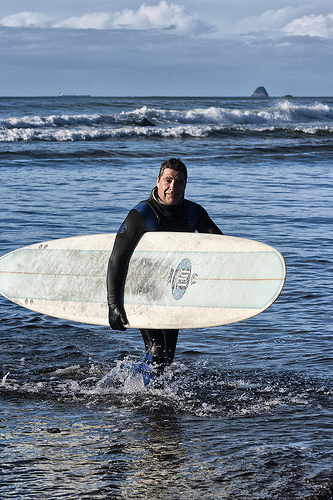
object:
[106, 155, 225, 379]
man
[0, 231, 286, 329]
surfboard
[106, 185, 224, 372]
suit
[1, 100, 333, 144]
wave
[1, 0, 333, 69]
sky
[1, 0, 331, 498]
photo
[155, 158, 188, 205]
head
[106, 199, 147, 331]
arm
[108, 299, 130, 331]
hand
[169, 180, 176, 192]
nose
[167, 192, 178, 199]
mouth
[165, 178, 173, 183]
eye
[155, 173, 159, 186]
ear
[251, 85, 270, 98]
island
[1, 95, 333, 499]
ocean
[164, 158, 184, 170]
hair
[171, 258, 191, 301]
logo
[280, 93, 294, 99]
ship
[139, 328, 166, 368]
leg